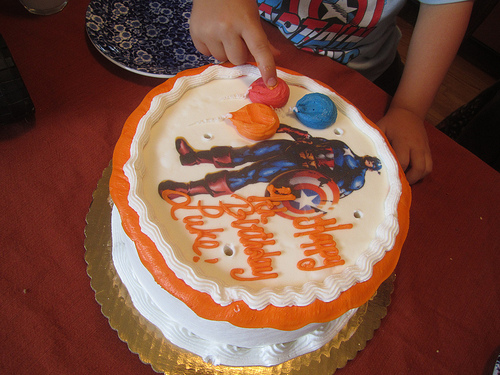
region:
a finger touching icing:
[185, 2, 287, 92]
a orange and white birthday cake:
[87, 55, 419, 374]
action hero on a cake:
[155, 122, 383, 209]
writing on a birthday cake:
[156, 172, 354, 287]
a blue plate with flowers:
[86, 0, 200, 72]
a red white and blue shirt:
[265, 2, 398, 59]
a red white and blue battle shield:
[270, 167, 340, 220]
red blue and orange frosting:
[230, 72, 340, 142]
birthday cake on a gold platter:
[87, 58, 419, 373]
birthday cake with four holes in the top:
[100, 59, 404, 374]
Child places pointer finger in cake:
[160, 11, 291, 111]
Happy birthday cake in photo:
[140, 40, 375, 370]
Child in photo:
[222, 0, 453, 110]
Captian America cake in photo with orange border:
[116, 57, 394, 357]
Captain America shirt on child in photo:
[203, 1, 412, 81]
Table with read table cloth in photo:
[0, 79, 494, 363]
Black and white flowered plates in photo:
[63, 0, 228, 87]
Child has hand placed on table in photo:
[357, 82, 454, 192]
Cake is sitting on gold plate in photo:
[70, 55, 422, 360]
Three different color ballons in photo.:
[65, 50, 408, 370]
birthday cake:
[99, 43, 414, 370]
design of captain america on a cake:
[151, 114, 388, 221]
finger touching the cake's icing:
[245, 34, 282, 96]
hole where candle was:
[220, 242, 235, 258]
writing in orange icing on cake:
[156, 180, 353, 289]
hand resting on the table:
[365, 99, 438, 194]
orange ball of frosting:
[228, 101, 280, 143]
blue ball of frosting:
[293, 88, 340, 131]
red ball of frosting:
[243, 73, 294, 111]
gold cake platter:
[73, 149, 410, 374]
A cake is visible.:
[92, 35, 360, 367]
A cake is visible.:
[175, 114, 422, 332]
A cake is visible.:
[235, 145, 355, 289]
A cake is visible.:
[207, 102, 338, 323]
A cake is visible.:
[120, 104, 314, 265]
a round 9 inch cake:
[81, 103, 426, 308]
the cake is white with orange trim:
[92, 40, 428, 316]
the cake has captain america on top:
[158, 120, 400, 207]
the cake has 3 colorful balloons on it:
[238, 65, 353, 142]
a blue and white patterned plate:
[73, 6, 233, 76]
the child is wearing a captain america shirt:
[263, 7, 413, 104]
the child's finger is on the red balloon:
[228, 18, 338, 110]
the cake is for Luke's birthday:
[157, 201, 363, 266]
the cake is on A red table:
[420, 266, 496, 336]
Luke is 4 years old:
[221, 147, 315, 214]